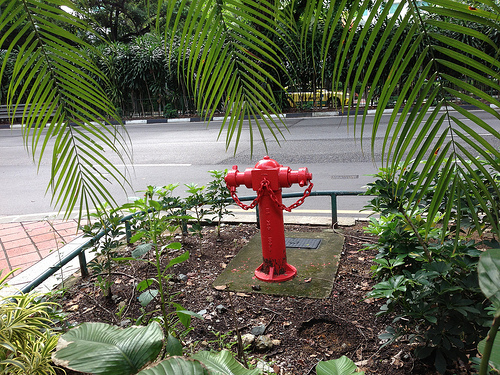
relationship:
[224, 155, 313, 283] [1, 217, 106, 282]
hydrant on sidewalk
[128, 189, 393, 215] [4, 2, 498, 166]
rail around plant area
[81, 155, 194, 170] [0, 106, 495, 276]
stripe on road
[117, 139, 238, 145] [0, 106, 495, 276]
stripe on road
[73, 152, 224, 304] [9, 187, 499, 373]
plant in enclosed area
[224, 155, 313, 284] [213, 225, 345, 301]
hydrant rests on block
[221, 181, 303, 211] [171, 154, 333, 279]
chain on back of hydrant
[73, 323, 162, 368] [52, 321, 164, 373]
lines in leaf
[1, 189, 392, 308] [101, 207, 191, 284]
rail around greenery